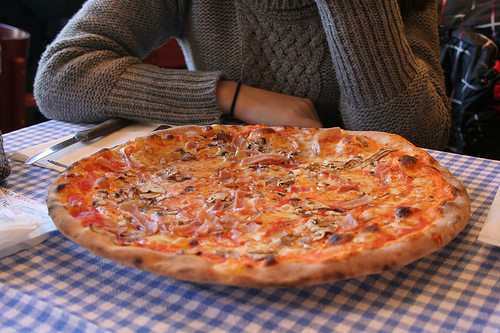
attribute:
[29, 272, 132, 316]
lines — blue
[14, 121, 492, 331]
cloth — table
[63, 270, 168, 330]
lines — blue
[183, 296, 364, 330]
lines — blue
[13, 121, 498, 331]
tablecloth — blue, white, checkered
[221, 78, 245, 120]
tie — black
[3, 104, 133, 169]
knife — one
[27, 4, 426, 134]
sweater — gray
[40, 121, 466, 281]
pizza — round, fresh, baked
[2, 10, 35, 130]
chair — wooden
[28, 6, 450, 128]
sweater — gray, knit, long-sleeved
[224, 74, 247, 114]
band — black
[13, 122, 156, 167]
paper — white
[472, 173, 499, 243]
napkin — folded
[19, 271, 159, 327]
cloth — blue, white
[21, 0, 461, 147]
sweater — long sleeve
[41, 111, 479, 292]
pizza — cooked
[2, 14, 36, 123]
garbage can — silver top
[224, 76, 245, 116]
scrunchie — black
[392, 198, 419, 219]
spot — dark